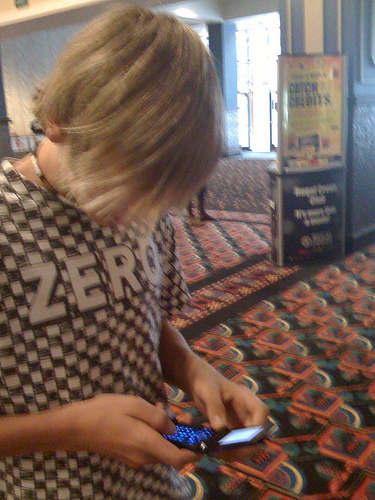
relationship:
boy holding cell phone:
[0, 3, 274, 499] [156, 412, 269, 454]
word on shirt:
[20, 237, 160, 328] [1, 156, 190, 498]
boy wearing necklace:
[0, 3, 274, 499] [29, 148, 83, 209]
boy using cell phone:
[0, 3, 274, 499] [156, 412, 269, 454]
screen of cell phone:
[214, 425, 264, 446] [156, 412, 269, 454]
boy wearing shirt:
[0, 3, 274, 499] [1, 156, 190, 498]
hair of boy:
[33, 3, 228, 247] [0, 3, 274, 499]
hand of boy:
[83, 392, 207, 474] [0, 3, 274, 499]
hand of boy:
[188, 366, 270, 437] [0, 3, 274, 499]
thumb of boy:
[199, 388, 229, 436] [0, 3, 274, 499]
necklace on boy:
[29, 148, 83, 209] [0, 3, 274, 499]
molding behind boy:
[207, 19, 245, 160] [0, 3, 274, 499]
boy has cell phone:
[0, 3, 274, 499] [156, 412, 269, 454]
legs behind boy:
[183, 184, 216, 223] [0, 3, 274, 499]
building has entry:
[5, 22, 373, 481] [234, 12, 283, 156]